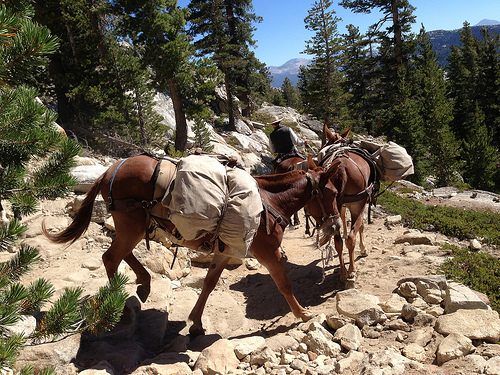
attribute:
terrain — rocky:
[10, 146, 496, 370]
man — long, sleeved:
[249, 95, 321, 178]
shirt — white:
[266, 125, 323, 157]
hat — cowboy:
[272, 113, 283, 131]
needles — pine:
[42, 297, 141, 337]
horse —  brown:
[40, 141, 346, 324]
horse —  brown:
[55, 124, 333, 318]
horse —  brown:
[50, 153, 345, 334]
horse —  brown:
[43, 116, 376, 329]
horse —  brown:
[38, 115, 402, 340]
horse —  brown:
[76, 133, 340, 330]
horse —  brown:
[88, 148, 347, 346]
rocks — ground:
[345, 280, 391, 328]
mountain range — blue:
[261, 53, 330, 94]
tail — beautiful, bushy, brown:
[42, 169, 103, 252]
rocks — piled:
[382, 267, 498, 370]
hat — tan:
[242, 102, 282, 127]